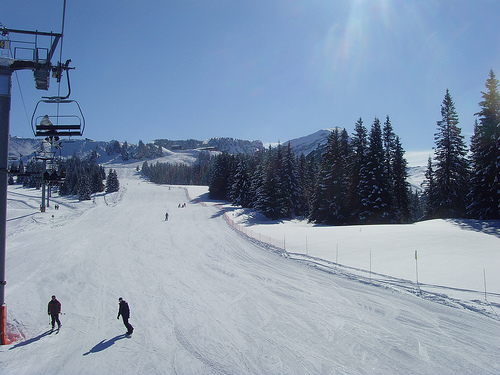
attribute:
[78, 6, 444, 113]
sky — blue, clear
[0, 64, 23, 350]
pole — grey and orange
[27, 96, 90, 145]
air lift — metal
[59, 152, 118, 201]
trees — distant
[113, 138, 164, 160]
trees — distant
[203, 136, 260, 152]
trees — distant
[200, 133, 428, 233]
trees — pine, tall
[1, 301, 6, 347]
base — orange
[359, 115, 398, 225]
trees — tall, green, evergreen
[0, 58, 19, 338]
beam — metal 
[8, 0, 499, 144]
sky — cloudless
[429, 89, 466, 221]
tree — tall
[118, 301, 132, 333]
clothing — dark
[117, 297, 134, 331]
clothes — dark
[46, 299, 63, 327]
clothes — dark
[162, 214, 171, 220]
clothes — dark